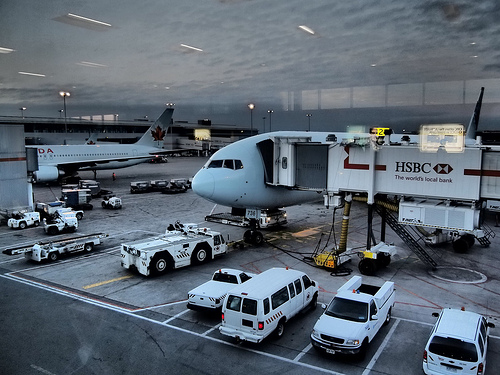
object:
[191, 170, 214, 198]
nose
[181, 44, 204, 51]
tube light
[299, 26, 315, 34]
tube light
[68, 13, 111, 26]
tube light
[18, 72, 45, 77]
tube light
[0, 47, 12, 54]
tube light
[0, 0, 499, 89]
ceiling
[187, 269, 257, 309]
truck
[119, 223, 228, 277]
truck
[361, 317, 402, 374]
lines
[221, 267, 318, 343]
commercial van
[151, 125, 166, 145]
leaf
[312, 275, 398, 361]
cars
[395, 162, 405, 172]
letters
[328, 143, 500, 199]
terminal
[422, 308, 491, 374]
cars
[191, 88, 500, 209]
plane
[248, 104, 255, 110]
lights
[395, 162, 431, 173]
hsbc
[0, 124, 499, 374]
airport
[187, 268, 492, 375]
row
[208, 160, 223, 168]
window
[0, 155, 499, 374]
ground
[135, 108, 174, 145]
tail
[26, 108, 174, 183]
airplane